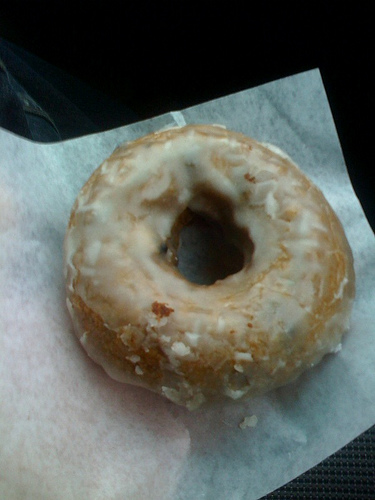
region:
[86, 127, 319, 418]
a donut on the paper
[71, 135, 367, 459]
a glazed donut on the paper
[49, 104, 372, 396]
a paper with a donut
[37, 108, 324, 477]
a paper with a glazed donut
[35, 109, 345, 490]
a donut that has been galzed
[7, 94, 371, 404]
a baked donut glazed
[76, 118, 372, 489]
a baked donut on a paper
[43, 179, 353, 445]
a cooked doughnut glazed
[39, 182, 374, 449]
a donut on a paper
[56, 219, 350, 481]
a baked doughnut on a papr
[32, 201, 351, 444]
a cooked doughnut on a paper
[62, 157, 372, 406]
a glazed doughnut on a paper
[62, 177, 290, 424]
a glazed paper doughnut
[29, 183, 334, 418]
a glazed cooked doughnut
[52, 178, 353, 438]
a doughnut that is glazed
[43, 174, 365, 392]
a baked donut that is glazed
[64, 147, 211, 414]
The left half of the duoghnut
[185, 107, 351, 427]
THe right half if the doughnut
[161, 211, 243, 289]
The hole in the doughnut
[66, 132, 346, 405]
The frosting of the doughnut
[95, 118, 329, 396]
The brown part of the doughnut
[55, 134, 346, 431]
A doughnut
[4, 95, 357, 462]
The parchment paper the doughnut is on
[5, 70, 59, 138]
The corner of the mans jeans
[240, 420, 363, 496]
The corner of the cars seat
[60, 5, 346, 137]
Empty blackness in the photo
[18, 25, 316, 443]
this is a donut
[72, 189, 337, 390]
this is a pastry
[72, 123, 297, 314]
the donut is glazed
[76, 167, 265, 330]
the glaze is white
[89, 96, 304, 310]
the donut is cooked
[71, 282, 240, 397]
the donut is light brown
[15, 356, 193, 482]
this is parchment paper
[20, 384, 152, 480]
the paper is white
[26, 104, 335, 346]
the donut is on the paper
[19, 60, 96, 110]
the background is black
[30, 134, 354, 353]
donut in the photo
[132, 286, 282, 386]
glaze on the donut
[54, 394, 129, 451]
paper under the donut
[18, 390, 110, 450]
white paper in photo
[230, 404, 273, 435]
icing on the paper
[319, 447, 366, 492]
surface next to the donut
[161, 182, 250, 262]
hole in middle of donut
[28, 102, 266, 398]
round donut in the photo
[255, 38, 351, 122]
corner of the paper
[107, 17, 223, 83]
black background of photo